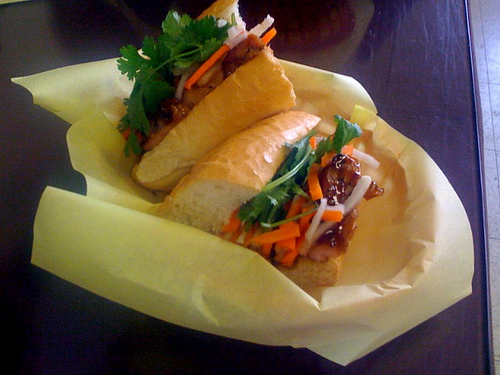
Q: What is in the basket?
A: Sandwich.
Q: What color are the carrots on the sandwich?
A: Orange.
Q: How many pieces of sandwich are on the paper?
A: Two.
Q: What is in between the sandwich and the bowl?
A: Paper.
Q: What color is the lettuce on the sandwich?
A: Green.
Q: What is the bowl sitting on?
A: Table.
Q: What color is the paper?
A: Yellow.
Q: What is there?
A: Sandwich.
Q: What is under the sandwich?
A: Paper.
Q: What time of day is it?
A: Lunch.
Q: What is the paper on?
A: Plate.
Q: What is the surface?
A: Table.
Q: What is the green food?
A: Lettuce.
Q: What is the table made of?
A: Wood.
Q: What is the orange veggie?
A: Carrots.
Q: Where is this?
A: Restaurant.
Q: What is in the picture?
A: A sandwich.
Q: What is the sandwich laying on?
A: Paper.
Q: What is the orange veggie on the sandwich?
A: Carrots.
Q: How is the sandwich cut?
A: In half.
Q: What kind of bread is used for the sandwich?
A: White bread.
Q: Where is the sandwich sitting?
A: On brown table.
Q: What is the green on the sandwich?
A: Lettuce.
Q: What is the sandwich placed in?
A: A basket.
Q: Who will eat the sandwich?
A: Person taking the photo.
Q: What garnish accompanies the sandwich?
A: Parsley.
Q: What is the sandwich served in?
A: Paper lined basket.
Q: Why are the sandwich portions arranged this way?
A: Not enough room.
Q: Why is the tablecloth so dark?
A: Won't show stains.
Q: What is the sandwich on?
A: Paper.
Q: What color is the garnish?
A: Green.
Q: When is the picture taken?
A: Daytime.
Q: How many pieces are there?
A: Two.